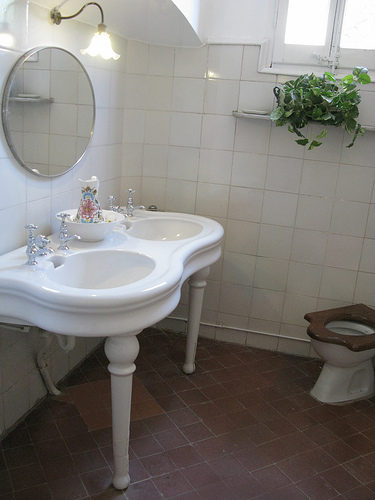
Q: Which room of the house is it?
A: It is a bathroom.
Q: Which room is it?
A: It is a bathroom.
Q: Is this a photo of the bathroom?
A: Yes, it is showing the bathroom.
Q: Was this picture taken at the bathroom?
A: Yes, it was taken in the bathroom.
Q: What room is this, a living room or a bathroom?
A: It is a bathroom.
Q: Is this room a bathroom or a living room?
A: It is a bathroom.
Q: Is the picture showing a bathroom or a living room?
A: It is showing a bathroom.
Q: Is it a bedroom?
A: No, it is a bathroom.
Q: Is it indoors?
A: Yes, it is indoors.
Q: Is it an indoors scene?
A: Yes, it is indoors.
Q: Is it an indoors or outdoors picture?
A: It is indoors.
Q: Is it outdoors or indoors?
A: It is indoors.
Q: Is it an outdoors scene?
A: No, it is indoors.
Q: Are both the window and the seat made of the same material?
A: No, the window is made of glass and the seat is made of wood.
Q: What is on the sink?
A: The pitcher is on the sink.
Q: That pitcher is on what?
A: The pitcher is on the sink.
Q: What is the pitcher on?
A: The pitcher is on the sink.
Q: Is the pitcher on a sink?
A: Yes, the pitcher is on a sink.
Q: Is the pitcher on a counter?
A: No, the pitcher is on a sink.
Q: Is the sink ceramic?
A: Yes, the sink is ceramic.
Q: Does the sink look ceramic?
A: Yes, the sink is ceramic.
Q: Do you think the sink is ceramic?
A: Yes, the sink is ceramic.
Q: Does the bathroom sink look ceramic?
A: Yes, the sink is ceramic.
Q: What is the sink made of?
A: The sink is made of porcelain.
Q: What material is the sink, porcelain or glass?
A: The sink is made of porcelain.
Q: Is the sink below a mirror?
A: Yes, the sink is below a mirror.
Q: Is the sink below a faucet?
A: No, the sink is below a mirror.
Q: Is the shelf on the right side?
A: Yes, the shelf is on the right of the image.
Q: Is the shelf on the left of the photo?
A: No, the shelf is on the right of the image.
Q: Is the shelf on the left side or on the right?
A: The shelf is on the right of the image.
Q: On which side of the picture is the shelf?
A: The shelf is on the right of the image.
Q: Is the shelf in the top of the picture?
A: Yes, the shelf is in the top of the image.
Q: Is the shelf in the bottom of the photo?
A: No, the shelf is in the top of the image.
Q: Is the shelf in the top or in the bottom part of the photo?
A: The shelf is in the top of the image.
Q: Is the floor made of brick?
A: Yes, the floor is made of brick.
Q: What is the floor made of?
A: The floor is made of brick.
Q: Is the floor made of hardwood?
A: No, the floor is made of brick.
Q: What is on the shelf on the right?
A: The plant is on the shelf.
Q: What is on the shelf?
A: The plant is on the shelf.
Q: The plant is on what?
A: The plant is on the shelf.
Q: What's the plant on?
A: The plant is on the shelf.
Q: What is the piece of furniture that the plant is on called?
A: The piece of furniture is a shelf.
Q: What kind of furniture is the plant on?
A: The plant is on the shelf.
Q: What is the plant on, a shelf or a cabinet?
A: The plant is on a shelf.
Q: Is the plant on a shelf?
A: Yes, the plant is on a shelf.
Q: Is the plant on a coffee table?
A: No, the plant is on a shelf.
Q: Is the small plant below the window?
A: Yes, the plant is below the window.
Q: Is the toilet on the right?
A: Yes, the toilet is on the right of the image.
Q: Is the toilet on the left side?
A: No, the toilet is on the right of the image.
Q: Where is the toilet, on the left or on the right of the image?
A: The toilet is on the right of the image.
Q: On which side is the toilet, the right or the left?
A: The toilet is on the right of the image.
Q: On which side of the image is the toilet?
A: The toilet is on the right of the image.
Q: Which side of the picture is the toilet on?
A: The toilet is on the right of the image.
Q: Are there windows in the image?
A: Yes, there is a window.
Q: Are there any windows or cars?
A: Yes, there is a window.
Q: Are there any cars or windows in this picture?
A: Yes, there is a window.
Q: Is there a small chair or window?
A: Yes, there is a small window.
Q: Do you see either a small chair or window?
A: Yes, there is a small window.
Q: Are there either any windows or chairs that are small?
A: Yes, the window is small.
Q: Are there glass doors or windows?
A: Yes, there is a glass window.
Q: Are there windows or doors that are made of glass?
A: Yes, the window is made of glass.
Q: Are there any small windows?
A: Yes, there is a small window.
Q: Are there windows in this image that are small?
A: Yes, there is a window that is small.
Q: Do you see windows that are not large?
A: Yes, there is a small window.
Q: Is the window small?
A: Yes, the window is small.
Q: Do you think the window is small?
A: Yes, the window is small.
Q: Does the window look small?
A: Yes, the window is small.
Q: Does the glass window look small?
A: Yes, the window is small.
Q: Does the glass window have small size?
A: Yes, the window is small.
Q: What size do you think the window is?
A: The window is small.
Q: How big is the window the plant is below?
A: The window is small.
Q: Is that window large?
A: No, the window is small.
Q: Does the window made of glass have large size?
A: No, the window is small.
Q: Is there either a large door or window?
A: No, there is a window but it is small.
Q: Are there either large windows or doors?
A: No, there is a window but it is small.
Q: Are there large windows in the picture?
A: No, there is a window but it is small.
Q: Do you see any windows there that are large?
A: No, there is a window but it is small.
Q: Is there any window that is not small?
A: No, there is a window but it is small.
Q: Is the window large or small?
A: The window is small.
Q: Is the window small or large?
A: The window is small.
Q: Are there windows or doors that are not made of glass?
A: No, there is a window but it is made of glass.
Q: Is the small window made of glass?
A: Yes, the window is made of glass.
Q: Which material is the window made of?
A: The window is made of glass.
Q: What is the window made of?
A: The window is made of glass.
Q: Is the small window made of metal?
A: No, the window is made of glass.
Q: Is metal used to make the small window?
A: No, the window is made of glass.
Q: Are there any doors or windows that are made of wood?
A: No, there is a window but it is made of glass.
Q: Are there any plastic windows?
A: No, there is a window but it is made of glass.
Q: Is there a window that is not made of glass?
A: No, there is a window but it is made of glass.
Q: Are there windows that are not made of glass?
A: No, there is a window but it is made of glass.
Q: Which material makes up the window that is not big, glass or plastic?
A: The window is made of glass.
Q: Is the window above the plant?
A: Yes, the window is above the plant.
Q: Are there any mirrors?
A: Yes, there is a mirror.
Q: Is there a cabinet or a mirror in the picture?
A: Yes, there is a mirror.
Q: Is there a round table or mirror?
A: Yes, there is a round mirror.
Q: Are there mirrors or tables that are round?
A: Yes, the mirror is round.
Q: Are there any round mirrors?
A: Yes, there is a round mirror.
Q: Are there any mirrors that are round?
A: Yes, there is a mirror that is round.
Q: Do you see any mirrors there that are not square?
A: Yes, there is a round mirror.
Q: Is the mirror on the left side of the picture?
A: Yes, the mirror is on the left of the image.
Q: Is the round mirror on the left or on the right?
A: The mirror is on the left of the image.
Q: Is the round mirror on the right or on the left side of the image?
A: The mirror is on the left of the image.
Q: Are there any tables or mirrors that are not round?
A: No, there is a mirror but it is round.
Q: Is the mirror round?
A: Yes, the mirror is round.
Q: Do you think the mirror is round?
A: Yes, the mirror is round.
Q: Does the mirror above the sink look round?
A: Yes, the mirror is round.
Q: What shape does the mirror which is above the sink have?
A: The mirror has round shape.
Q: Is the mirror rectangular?
A: No, the mirror is round.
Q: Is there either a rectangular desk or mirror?
A: No, there is a mirror but it is round.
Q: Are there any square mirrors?
A: No, there is a mirror but it is round.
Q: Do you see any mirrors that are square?
A: No, there is a mirror but it is round.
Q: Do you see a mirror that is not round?
A: No, there is a mirror but it is round.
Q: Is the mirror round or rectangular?
A: The mirror is round.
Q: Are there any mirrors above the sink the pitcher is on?
A: Yes, there is a mirror above the sink.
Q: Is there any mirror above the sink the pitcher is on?
A: Yes, there is a mirror above the sink.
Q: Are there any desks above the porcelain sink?
A: No, there is a mirror above the sink.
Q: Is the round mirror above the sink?
A: Yes, the mirror is above the sink.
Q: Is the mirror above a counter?
A: No, the mirror is above the sink.